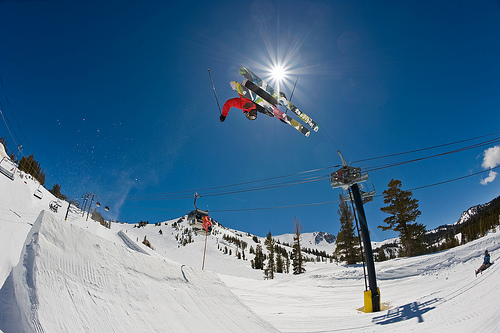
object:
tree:
[378, 176, 426, 254]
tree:
[332, 192, 365, 266]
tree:
[289, 215, 309, 275]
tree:
[263, 230, 275, 280]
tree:
[250, 243, 268, 270]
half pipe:
[13, 207, 277, 333]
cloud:
[474, 144, 500, 186]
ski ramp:
[0, 207, 281, 333]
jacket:
[222, 96, 258, 117]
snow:
[0, 160, 500, 333]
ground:
[0, 203, 500, 333]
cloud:
[60, 96, 175, 214]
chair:
[186, 209, 215, 235]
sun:
[260, 60, 296, 85]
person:
[473, 248, 494, 275]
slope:
[305, 228, 500, 333]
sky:
[0, 0, 500, 237]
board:
[237, 65, 321, 133]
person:
[217, 79, 287, 124]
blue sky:
[0, 0, 500, 229]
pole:
[351, 185, 382, 313]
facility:
[10, 206, 287, 333]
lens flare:
[215, 27, 331, 109]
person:
[195, 211, 206, 222]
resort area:
[0, 147, 500, 333]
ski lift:
[186, 193, 214, 237]